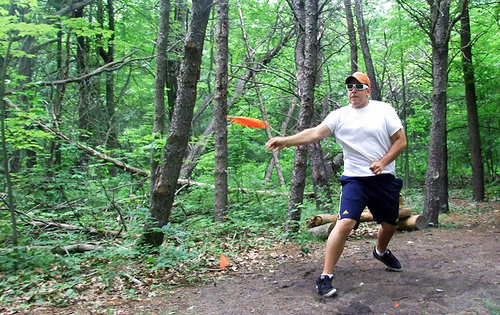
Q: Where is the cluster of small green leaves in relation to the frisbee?
A: Down on the left.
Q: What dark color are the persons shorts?
A: Blue.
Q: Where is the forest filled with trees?
A: All around the man.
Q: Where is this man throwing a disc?
A: Forest.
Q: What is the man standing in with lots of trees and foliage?
A: Forest.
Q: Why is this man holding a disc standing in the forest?
A: He's playing disc golf.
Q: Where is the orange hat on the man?
A: Head.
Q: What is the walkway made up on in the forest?
A: Dirt.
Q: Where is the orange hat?
A: Man's head.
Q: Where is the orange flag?
A: Ground.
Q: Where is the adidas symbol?
A: On shorts.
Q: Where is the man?
A: In woods.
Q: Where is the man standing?
A: On path.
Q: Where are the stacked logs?
A: Behind man.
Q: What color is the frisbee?
A: Orange.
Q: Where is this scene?
A: Forest.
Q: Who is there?
A: A person.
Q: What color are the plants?
A: Green.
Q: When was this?
A: Daytime.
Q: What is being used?
A: Frisbee.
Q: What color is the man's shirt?
A: White.